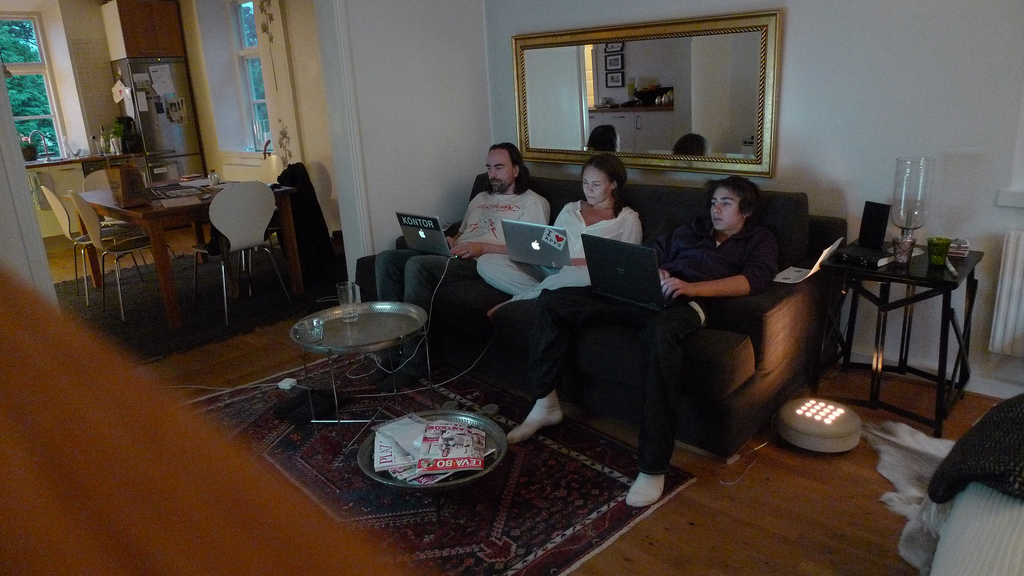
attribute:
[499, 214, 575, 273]
laptop — silver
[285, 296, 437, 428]
table — round, silver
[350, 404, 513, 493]
tray — metal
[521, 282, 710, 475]
pants — black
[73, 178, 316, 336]
table — wood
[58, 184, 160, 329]
chair — metal, white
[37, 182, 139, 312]
chair — metal, white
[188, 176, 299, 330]
chair — metal, white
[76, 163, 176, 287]
chair — metal, white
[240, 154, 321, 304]
chair — metal, white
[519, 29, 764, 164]
wall mirror — long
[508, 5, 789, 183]
framing — gold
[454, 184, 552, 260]
shirt — white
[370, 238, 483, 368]
jeans — blue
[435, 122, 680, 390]
woman — cross legged, sitting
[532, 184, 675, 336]
clothing — white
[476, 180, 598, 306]
laptop — silver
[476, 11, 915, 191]
mirror — hanging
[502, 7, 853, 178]
mirror — gold framed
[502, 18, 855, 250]
mirror — reflecting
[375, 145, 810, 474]
people — sitting, three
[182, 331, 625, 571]
rug — dark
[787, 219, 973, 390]
table — small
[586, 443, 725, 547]
sock — white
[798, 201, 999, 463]
table — black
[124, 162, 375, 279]
chair — white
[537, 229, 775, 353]
computer — laptop